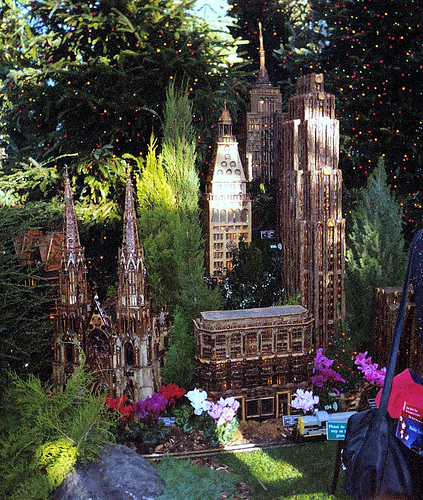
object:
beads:
[0, 0, 422, 224]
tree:
[355, 161, 403, 282]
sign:
[327, 421, 347, 441]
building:
[190, 305, 314, 424]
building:
[51, 163, 112, 399]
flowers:
[288, 388, 320, 415]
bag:
[375, 368, 423, 421]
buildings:
[84, 291, 115, 399]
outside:
[0, 0, 423, 500]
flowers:
[105, 382, 240, 422]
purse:
[342, 230, 423, 500]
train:
[292, 410, 358, 445]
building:
[13, 230, 63, 287]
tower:
[217, 99, 237, 142]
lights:
[335, 28, 414, 104]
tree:
[136, 76, 202, 296]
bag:
[341, 408, 423, 500]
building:
[279, 71, 349, 346]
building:
[103, 166, 176, 405]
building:
[246, 22, 281, 179]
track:
[140, 436, 299, 463]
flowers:
[354, 351, 386, 388]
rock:
[46, 440, 167, 500]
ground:
[2, 388, 423, 500]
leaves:
[0, 394, 88, 470]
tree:
[0, 0, 204, 161]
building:
[199, 97, 253, 281]